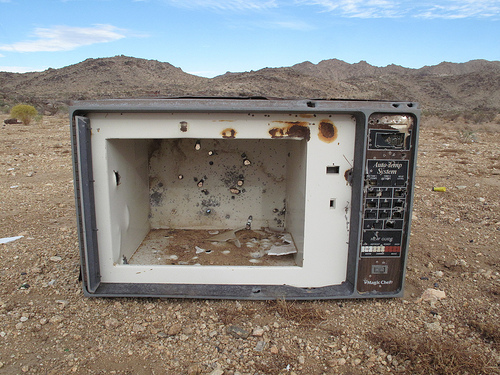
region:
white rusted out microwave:
[62, 86, 417, 306]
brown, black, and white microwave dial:
[352, 103, 424, 300]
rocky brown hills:
[0, 54, 499, 128]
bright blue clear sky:
[1, 1, 498, 81]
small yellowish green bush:
[7, 96, 42, 136]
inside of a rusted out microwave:
[101, 134, 307, 265]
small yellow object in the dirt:
[430, 182, 450, 196]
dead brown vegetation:
[374, 323, 496, 373]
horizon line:
[0, 50, 499, 88]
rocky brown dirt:
[2, 111, 499, 373]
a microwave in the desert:
[50, 85, 434, 299]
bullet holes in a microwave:
[163, 142, 264, 198]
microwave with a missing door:
[52, 80, 446, 333]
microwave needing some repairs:
[62, 79, 444, 316]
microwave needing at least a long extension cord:
[52, 84, 439, 311]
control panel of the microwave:
[352, 150, 417, 286]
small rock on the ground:
[408, 285, 456, 315]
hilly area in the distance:
[5, 55, 499, 110]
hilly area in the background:
[7, 56, 498, 118]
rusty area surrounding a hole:
[307, 115, 340, 149]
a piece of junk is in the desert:
[68, 91, 420, 305]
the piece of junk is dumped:
[63, 95, 420, 303]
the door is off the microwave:
[68, 91, 419, 301]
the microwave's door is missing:
[66, 92, 426, 307]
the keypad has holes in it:
[351, 105, 414, 302]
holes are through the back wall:
[146, 145, 287, 235]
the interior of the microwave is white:
[96, 115, 353, 287]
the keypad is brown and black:
[353, 97, 413, 299]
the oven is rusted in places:
[218, 114, 350, 152]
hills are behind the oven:
[0, 36, 499, 305]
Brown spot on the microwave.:
[313, 119, 338, 148]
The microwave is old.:
[65, 80, 423, 301]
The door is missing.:
[50, 98, 460, 354]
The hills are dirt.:
[20, 49, 498, 114]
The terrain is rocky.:
[65, 308, 382, 374]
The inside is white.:
[50, 103, 385, 306]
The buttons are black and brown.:
[363, 101, 425, 323]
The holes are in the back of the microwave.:
[135, 112, 326, 261]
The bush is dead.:
[9, 91, 50, 143]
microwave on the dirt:
[26, 79, 448, 323]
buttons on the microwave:
[360, 178, 407, 236]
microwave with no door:
[70, 111, 320, 264]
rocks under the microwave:
[208, 318, 270, 358]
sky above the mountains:
[326, 16, 383, 46]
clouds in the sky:
[40, 16, 132, 60]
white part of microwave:
[303, 183, 344, 251]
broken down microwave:
[1, 71, 466, 321]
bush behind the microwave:
[0, 97, 45, 137]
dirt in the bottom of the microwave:
[181, 217, 274, 285]